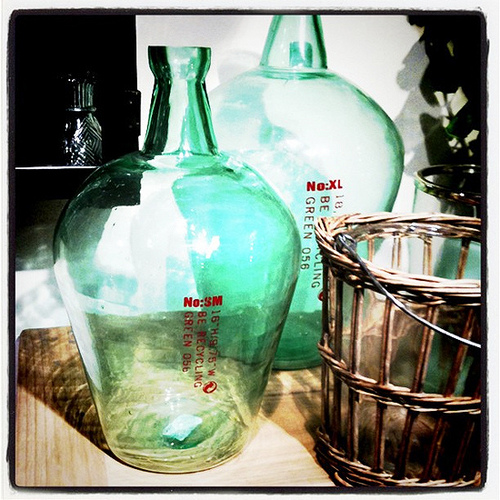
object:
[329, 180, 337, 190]
letter x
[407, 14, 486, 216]
plant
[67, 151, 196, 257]
reflection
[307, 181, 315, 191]
n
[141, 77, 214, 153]
neck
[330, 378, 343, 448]
straw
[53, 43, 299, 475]
bottle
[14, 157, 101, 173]
shelf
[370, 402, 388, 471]
straw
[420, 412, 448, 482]
straw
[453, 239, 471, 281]
straw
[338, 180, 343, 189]
l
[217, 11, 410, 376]
jar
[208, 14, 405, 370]
bottle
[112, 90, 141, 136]
black hinge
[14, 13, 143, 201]
cabinet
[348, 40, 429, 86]
shadow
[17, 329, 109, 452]
shadow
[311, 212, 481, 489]
basket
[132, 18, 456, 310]
wall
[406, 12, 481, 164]
leaves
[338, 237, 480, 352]
handle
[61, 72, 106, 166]
vase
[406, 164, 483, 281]
glass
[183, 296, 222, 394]
print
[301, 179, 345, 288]
print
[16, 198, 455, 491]
table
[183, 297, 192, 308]
letter n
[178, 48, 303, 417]
tint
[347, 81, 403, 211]
tint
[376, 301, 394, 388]
straw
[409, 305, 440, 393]
straw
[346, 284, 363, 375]
straw